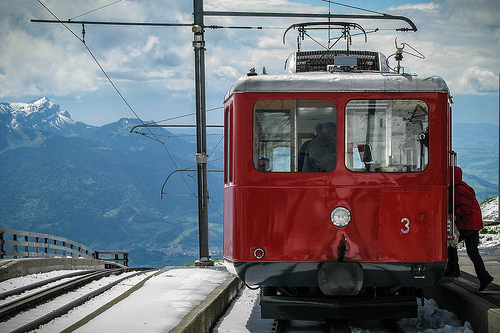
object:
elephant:
[448, 157, 488, 236]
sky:
[0, 0, 498, 140]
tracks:
[2, 264, 156, 333]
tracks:
[269, 313, 405, 331]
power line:
[189, 0, 210, 267]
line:
[84, 45, 149, 122]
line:
[163, 143, 182, 173]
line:
[178, 170, 197, 197]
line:
[38, 2, 67, 21]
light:
[330, 206, 350, 228]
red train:
[220, 49, 457, 331]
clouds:
[3, 0, 498, 91]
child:
[447, 166, 495, 293]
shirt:
[451, 166, 485, 233]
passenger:
[298, 122, 337, 173]